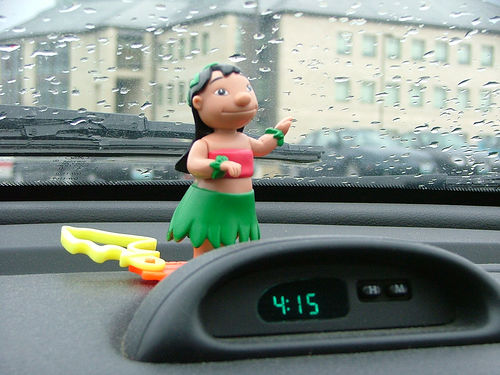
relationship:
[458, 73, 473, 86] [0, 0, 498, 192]
raindrop on windshield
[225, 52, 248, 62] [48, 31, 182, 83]
drop of water